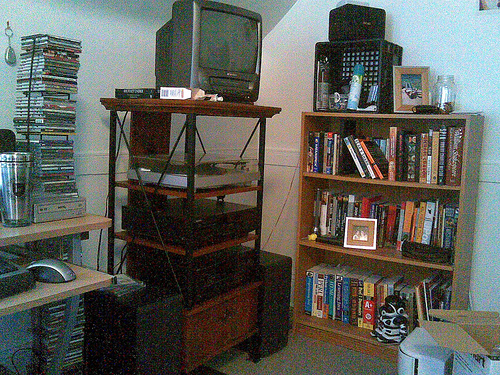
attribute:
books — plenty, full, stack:
[310, 127, 478, 331]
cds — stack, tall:
[7, 19, 108, 212]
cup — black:
[2, 135, 40, 243]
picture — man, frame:
[342, 211, 396, 257]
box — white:
[421, 289, 498, 375]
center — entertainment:
[74, 46, 324, 355]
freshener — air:
[314, 55, 384, 115]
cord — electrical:
[92, 213, 123, 264]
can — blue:
[335, 41, 386, 131]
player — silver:
[142, 146, 276, 190]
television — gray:
[62, 9, 292, 124]